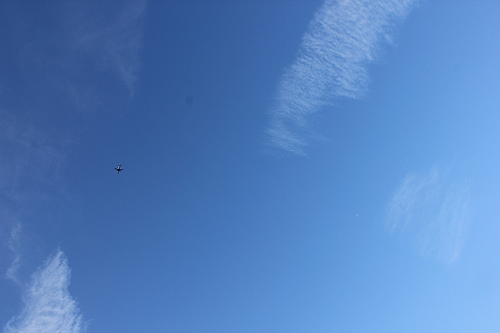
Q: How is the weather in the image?
A: It is clear.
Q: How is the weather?
A: It is clear.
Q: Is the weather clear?
A: Yes, it is clear.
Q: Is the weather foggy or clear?
A: It is clear.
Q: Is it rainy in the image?
A: No, it is clear.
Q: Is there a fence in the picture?
A: No, there are no fences.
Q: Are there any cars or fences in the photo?
A: No, there are no fences or cars.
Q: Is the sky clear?
A: Yes, the sky is clear.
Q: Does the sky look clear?
A: Yes, the sky is clear.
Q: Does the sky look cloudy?
A: No, the sky is clear.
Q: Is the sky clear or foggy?
A: The sky is clear.